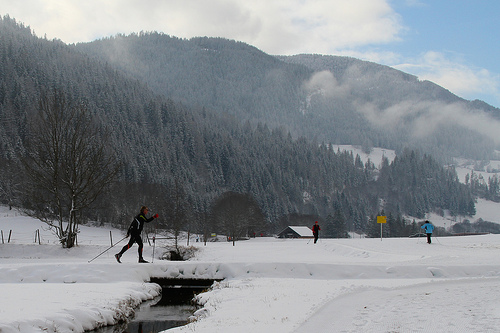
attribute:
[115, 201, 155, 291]
person — standing, here, walking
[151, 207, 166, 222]
glove — red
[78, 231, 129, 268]
pole — long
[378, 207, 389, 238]
sign — yellow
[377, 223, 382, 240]
post — grey, yellow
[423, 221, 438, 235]
coat — blue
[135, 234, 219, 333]
creek — here, small, running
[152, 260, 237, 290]
bridge — here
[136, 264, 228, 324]
river — here, frozen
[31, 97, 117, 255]
tree — here, leafless, bare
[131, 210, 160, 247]
jacket — here, blue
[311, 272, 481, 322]
line — here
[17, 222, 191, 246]
fence — here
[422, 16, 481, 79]
sky — blue, cloudy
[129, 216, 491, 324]
field — here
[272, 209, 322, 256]
building — here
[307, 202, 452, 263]
people — here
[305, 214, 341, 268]
man — here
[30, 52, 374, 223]
mountain — covered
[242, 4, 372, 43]
cloud — white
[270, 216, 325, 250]
cottage — small